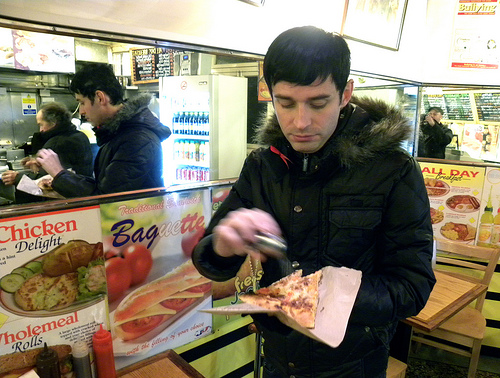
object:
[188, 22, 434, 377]
someone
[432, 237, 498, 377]
chair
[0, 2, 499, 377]
restaurant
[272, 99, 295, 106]
eye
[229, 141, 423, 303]
coat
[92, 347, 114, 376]
ketchup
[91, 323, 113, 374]
bottle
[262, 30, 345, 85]
hair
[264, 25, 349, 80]
black hair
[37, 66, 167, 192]
man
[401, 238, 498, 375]
wooden chair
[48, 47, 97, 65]
mirror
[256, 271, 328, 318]
pizza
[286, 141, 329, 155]
jaw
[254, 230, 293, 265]
shaker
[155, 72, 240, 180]
cooler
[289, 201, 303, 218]
button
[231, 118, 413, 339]
jacket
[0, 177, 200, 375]
wall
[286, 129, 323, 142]
mouth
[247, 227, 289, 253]
spice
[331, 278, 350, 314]
paper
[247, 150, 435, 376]
black jacket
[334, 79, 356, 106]
ear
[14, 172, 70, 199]
brown napkin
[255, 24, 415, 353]
person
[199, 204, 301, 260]
hand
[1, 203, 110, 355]
sign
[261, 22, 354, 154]
head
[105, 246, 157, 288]
photo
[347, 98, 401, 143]
fur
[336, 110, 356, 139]
hood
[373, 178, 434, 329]
arm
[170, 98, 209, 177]
drinks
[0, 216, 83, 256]
words